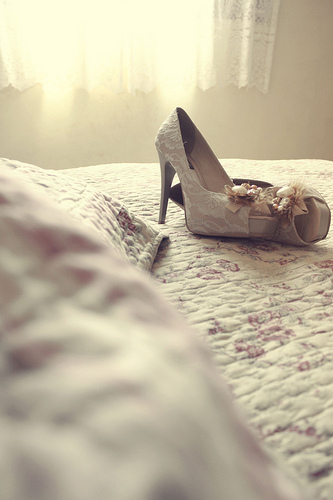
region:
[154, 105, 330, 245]
high heel shoes on bed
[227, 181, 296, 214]
decoration on top of shoes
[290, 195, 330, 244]
open toe on tipped over shoe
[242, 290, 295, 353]
flower designs on bed spread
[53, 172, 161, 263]
corner of pillow on bed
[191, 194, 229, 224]
lace design on shoe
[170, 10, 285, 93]
white lace curtain on window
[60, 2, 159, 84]
sunlight shining through curtain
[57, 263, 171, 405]
blurry object in foreground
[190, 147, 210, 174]
inside of standing shoe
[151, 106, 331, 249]
The shoes on the bed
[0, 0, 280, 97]
The curtains covering the window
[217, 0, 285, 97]
The part of the curtains with no light coming through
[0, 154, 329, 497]
The floral print bed cover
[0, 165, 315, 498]
The out of focus portion of the blanket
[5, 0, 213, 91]
The portion of the curtain that light is coming through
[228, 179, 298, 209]
The decoration over the toes of the shoes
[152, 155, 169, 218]
The heel on the back of the shoe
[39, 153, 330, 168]
Edge of the bed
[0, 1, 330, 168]
The wall in the background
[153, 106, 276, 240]
a shoe on a bed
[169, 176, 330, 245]
a shoe on bed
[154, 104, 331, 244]
two shoes on a bed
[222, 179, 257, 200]
a decoration on a shoe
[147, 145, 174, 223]
a heel of a shoe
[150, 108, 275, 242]
a high heeled shoe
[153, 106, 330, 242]
two high heeled shoes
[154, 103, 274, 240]
shoe with four inch heel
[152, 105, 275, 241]
an open toed shoe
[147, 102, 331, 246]
two open toed shoes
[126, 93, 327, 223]
High heels on the bed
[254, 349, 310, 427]
A comforter on the bed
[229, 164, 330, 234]
Flowers on the shoes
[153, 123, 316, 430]
Wedding shoes on the bed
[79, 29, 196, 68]
Sunlight coming in the window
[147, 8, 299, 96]
Lace curtains in the window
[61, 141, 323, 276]
Shoes on the bed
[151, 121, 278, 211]
Lace on the shoes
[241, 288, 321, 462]
Floral pattern on the bed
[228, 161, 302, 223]
Toe-less heels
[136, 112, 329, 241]
High heeled shoes on bed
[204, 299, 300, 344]
Rose pattern on bed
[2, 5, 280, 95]
White lace curtains on window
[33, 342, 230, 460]
Blurred blanket on bed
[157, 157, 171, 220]
Four inch heel on shoe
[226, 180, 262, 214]
Flower on top of shoe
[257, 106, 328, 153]
Cream colored wall in room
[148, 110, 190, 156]
lace pattern on shoes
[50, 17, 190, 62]
Sunshine coming in window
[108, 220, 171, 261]
Corner of blanket